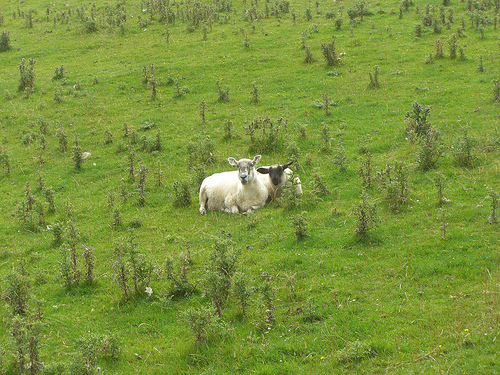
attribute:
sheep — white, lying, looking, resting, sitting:
[194, 157, 267, 216]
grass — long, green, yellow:
[3, 3, 500, 375]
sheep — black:
[258, 161, 303, 195]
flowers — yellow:
[61, 141, 105, 179]